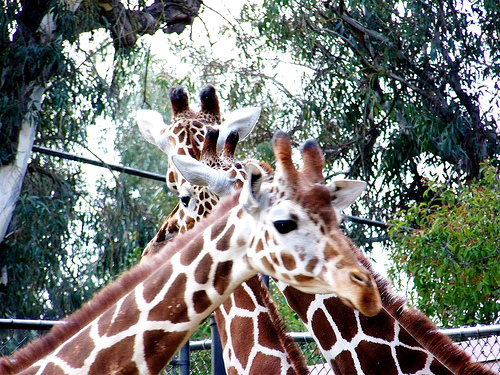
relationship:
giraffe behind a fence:
[0, 129, 383, 374] [0, 317, 499, 374]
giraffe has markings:
[0, 129, 383, 374] [0, 129, 384, 374]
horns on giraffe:
[272, 130, 324, 188] [0, 129, 383, 374]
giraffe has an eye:
[0, 129, 383, 374] [272, 220, 298, 234]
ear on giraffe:
[239, 165, 264, 215] [0, 129, 383, 374]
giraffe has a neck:
[0, 129, 383, 374] [0, 186, 259, 373]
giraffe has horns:
[0, 129, 383, 374] [272, 130, 324, 188]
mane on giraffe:
[1, 190, 243, 373] [0, 129, 383, 374]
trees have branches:
[0, 0, 497, 375] [0, 1, 499, 373]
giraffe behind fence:
[0, 129, 383, 374] [0, 317, 499, 374]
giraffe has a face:
[0, 129, 383, 374] [250, 174, 382, 315]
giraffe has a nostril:
[0, 129, 383, 374] [350, 271, 365, 283]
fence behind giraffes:
[0, 317, 499, 374] [1, 85, 499, 373]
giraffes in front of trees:
[1, 85, 499, 373] [0, 0, 497, 375]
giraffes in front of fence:
[1, 85, 499, 373] [0, 317, 499, 374]